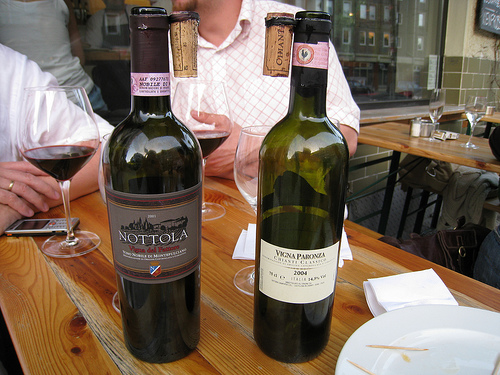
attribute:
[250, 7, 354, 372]
bottle — Light green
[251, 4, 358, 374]
green bottle — green , dark 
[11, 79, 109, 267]
glass — semi empty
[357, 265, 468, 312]
napkin — folded 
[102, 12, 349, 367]
bottles — wine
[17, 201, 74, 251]
phone — silver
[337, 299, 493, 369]
plate — dirty , white 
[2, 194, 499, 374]
bar — Light wood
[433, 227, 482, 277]
bag — brown , leather 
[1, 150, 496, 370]
table — wooden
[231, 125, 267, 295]
glass — empty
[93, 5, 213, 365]
bottle — dark green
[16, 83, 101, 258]
clear glass — clear 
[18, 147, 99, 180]
red wine — red 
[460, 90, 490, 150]
clear glass — stemmed , clear 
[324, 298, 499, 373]
plate — empty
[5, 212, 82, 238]
cellphone — silver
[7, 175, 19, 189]
ring — gold 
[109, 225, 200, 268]
writing — red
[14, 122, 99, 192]
wine — red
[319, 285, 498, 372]
plate — white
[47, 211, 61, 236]
button — red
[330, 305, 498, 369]
plate — white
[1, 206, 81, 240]
cell phone — silver 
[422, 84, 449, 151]
glass — clear , stemmed 